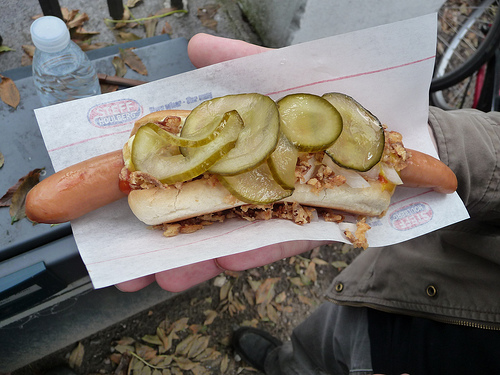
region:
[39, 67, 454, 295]
Hot dog in man's hand.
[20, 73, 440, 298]
hot dog with a bun.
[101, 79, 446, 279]
Pickles on the hot dog.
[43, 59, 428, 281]
Hot dog on the short bun.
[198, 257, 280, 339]
Leaves on the ground.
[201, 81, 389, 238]
Green pickles on the hot dog.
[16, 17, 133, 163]
Water bottle on the ground.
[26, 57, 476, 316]
Paper with a hot dog.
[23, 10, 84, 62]
Cap on the bottle.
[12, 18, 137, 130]
Clear bottle.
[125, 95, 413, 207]
slices of pickles on sandwich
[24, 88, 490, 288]
one piece of hotdog sandwich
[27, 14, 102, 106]
Clear plastic bottle with white cap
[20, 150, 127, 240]
Left end of a sausage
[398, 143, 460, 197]
Right end of a sausage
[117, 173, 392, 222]
Bottom of the bun underneath the hot dog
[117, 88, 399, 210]
Green pickles on top of the hot dog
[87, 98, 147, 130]
Red, white, and blue logo on the wax paper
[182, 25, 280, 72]
Person's white thumb underneath the hot dog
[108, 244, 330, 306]
Person's three fingers underneath the wax paper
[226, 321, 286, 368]
Black shoe at the bottom of the image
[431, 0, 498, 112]
Wheels of the bike next to the person's sleeve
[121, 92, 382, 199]
Cucumbers on the hotdog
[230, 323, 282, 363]
A black shoe on the persons foot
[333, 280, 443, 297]
Buttons on the jacket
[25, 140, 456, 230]
A hotdog between the buns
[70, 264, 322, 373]
Leaves on the ground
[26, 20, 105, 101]
A water bottle near the hotdog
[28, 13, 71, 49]
A white cap on the water bottle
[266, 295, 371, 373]
The person is wearing gray pants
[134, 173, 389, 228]
A bun beneath the cucumbers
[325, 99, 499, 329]
The person is wearing a jacket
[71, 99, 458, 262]
Pickels on top of a hot dog.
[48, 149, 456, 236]
a hot dog garnished with pickles.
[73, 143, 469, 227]
A hot dog smuthered with toppings.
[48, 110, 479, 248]
A hot dog placed on paper.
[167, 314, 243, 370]
Leaves scattered on the ground.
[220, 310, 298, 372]
A person wearing black shoes.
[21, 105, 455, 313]
A person holding a hot dog.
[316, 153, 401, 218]
Onions resting under pickles.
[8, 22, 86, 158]
Bottled water sitting on top of a table.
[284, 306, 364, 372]
a person wearing grey pants.